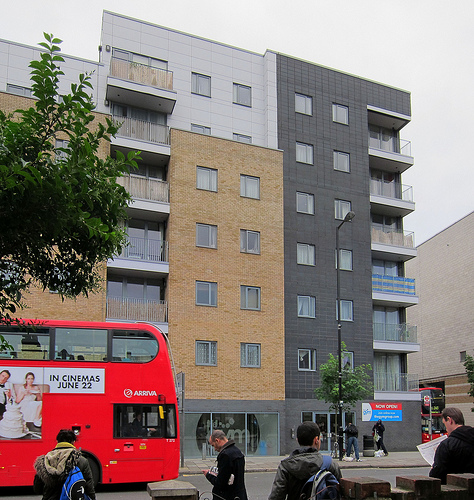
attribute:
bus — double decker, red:
[1, 315, 181, 489]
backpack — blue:
[61, 467, 88, 499]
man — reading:
[416, 408, 474, 476]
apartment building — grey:
[284, 56, 419, 407]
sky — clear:
[412, 0, 472, 210]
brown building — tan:
[168, 127, 285, 400]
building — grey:
[277, 53, 424, 450]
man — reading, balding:
[205, 429, 249, 500]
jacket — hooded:
[34, 447, 96, 498]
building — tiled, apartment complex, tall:
[176, 32, 424, 455]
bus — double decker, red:
[412, 385, 447, 445]